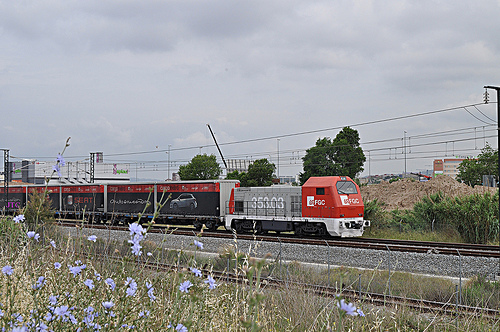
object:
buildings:
[3, 158, 131, 184]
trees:
[453, 140, 500, 187]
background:
[0, 75, 499, 243]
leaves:
[319, 156, 328, 166]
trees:
[224, 158, 277, 187]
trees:
[178, 151, 223, 180]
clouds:
[0, 0, 499, 173]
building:
[431, 155, 476, 180]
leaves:
[340, 142, 353, 153]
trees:
[297, 125, 366, 186]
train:
[0, 175, 372, 238]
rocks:
[43, 224, 499, 281]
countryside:
[0, 0, 499, 330]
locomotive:
[223, 175, 371, 239]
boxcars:
[0, 178, 242, 221]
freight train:
[0, 175, 372, 239]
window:
[315, 186, 324, 194]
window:
[334, 180, 357, 194]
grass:
[0, 230, 499, 331]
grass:
[363, 205, 499, 244]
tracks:
[0, 238, 499, 331]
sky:
[19, 7, 301, 131]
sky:
[260, 0, 499, 130]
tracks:
[0, 216, 499, 259]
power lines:
[0, 84, 499, 181]